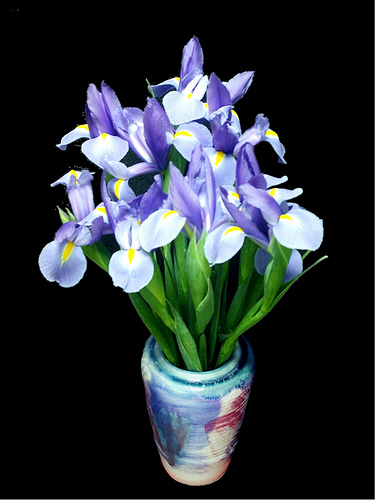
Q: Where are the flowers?
A: In the vase.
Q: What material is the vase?
A: Ceramic.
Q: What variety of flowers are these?
A: Iris.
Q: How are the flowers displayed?
A: In a vase.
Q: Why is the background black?
A: Photographer posed this picture.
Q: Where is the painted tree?
A: On the vase.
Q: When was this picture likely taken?
A: Spring.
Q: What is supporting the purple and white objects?
A: Green stems.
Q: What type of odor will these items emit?
A: Floral.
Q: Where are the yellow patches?
A: In the centers of the flowers.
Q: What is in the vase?
A: Flowers.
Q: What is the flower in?
A: Vase.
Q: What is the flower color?
A: Purple.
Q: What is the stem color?
A: Green.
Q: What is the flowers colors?
A: Purple, white and yellow.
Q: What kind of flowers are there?
A: Purple flowers.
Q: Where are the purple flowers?
A: In a jar.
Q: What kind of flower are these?
A: Purple irises.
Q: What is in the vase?
A: Purple with yellow and white flowers.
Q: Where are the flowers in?
A: A ceramic vase.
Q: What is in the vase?
A: Flowers.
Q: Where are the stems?
A: On the flowers.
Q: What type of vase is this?
A: Multi colored vase.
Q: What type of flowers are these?
A: Spring flowers.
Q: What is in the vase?
A: Fresh flowers.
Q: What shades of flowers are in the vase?
A: Purple with yellow and white centers.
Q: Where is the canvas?
A: Behind the vase.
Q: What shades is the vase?
A: Multi color.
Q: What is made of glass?
A: The vase.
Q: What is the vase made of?
A: Glass.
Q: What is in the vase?
A: Flowers.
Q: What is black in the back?
A: Backdrop.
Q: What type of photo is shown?
A: Painting.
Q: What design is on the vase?
A: Colorful print.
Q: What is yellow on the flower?
A: Nectar.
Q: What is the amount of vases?
A: One.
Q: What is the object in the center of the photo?
A: Vase.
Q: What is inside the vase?
A: Flowers.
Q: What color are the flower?
A: Purple, yellow and white.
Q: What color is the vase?
A: Silver and red.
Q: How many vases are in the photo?
A: One.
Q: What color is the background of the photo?
A: Black.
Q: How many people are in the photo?
A: None.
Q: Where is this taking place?
A: On a black surface.